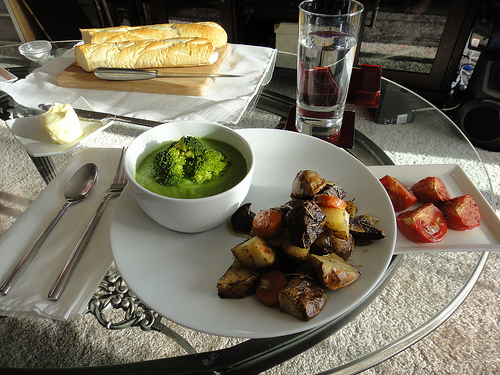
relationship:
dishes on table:
[98, 107, 400, 335] [0, 37, 499, 374]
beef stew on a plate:
[215, 168, 387, 328] [104, 121, 402, 344]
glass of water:
[291, 0, 360, 148] [294, 28, 353, 143]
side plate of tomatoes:
[361, 154, 499, 261] [378, 173, 477, 248]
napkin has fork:
[1, 141, 139, 335] [45, 144, 135, 305]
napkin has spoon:
[1, 141, 139, 335] [3, 161, 102, 302]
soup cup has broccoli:
[119, 115, 263, 244] [150, 133, 229, 189]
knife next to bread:
[90, 62, 251, 87] [71, 18, 235, 72]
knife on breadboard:
[90, 62, 251, 87] [49, 40, 239, 100]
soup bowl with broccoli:
[119, 115, 263, 244] [150, 133, 229, 189]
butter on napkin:
[37, 100, 85, 148] [6, 92, 115, 164]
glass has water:
[291, 0, 360, 148] [294, 28, 353, 143]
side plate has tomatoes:
[361, 154, 499, 261] [378, 173, 477, 248]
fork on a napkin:
[45, 144, 135, 305] [1, 141, 139, 335]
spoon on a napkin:
[3, 161, 102, 302] [1, 141, 139, 335]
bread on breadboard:
[71, 18, 235, 72] [49, 40, 239, 100]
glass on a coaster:
[291, 0, 360, 148] [280, 101, 363, 152]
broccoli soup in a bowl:
[133, 133, 248, 201] [119, 115, 263, 244]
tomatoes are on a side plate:
[378, 173, 477, 248] [361, 154, 499, 261]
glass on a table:
[291, 0, 360, 148] [0, 37, 499, 374]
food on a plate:
[215, 168, 387, 328] [104, 121, 402, 344]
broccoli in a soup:
[150, 133, 229, 189] [133, 133, 248, 201]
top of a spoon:
[61, 162, 105, 207] [3, 161, 102, 302]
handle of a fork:
[52, 190, 109, 308] [45, 144, 135, 305]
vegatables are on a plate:
[215, 168, 387, 328] [104, 121, 402, 344]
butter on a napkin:
[37, 100, 85, 148] [6, 92, 115, 164]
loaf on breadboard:
[70, 37, 221, 75] [49, 40, 239, 100]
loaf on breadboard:
[79, 18, 230, 50] [49, 40, 239, 100]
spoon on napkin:
[3, 161, 102, 302] [1, 141, 139, 335]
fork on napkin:
[45, 144, 135, 305] [1, 141, 139, 335]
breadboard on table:
[49, 40, 239, 100] [0, 37, 499, 374]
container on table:
[16, 37, 62, 66] [0, 37, 499, 374]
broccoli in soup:
[150, 133, 229, 189] [133, 133, 248, 201]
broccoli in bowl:
[150, 133, 229, 189] [119, 115, 263, 244]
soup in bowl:
[133, 133, 248, 201] [119, 115, 263, 244]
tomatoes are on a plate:
[378, 173, 477, 248] [361, 154, 499, 261]